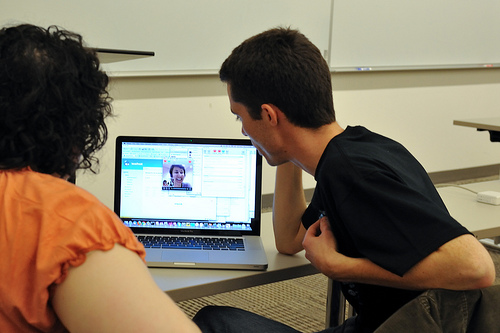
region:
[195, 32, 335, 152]
face of the person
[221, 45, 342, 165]
face of the boy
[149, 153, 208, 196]
a picture in computer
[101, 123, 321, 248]
a cool computer scren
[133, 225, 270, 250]
a key board connected to computer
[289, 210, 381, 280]
hand of the person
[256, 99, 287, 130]
ear of the person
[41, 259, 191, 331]
hand of the girl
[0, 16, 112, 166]
hairs of the girl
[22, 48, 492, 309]
two persons watching computer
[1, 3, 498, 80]
part of a white dry erase board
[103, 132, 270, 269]
a gray laptop computer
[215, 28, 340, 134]
a man's short cut hair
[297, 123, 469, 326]
part of a man's black shirt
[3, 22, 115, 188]
a woman's curly hair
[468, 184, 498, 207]
part of a white computer mouse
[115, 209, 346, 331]
part of a table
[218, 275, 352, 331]
a portion of carpet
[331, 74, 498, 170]
part of a white painted wall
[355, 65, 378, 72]
a blue and white marker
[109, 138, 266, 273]
small lap top computer on desk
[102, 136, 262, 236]
screen of laptop computer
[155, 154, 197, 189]
skype open on computer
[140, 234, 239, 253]
black computer key board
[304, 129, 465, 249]
black t-shirt on man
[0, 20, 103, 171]
curly black hair on head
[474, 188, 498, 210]
white power supply on table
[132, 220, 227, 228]
tabs open at bottom of screen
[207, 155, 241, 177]
text box open on screen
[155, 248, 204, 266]
silver track pad on front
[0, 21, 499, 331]
Man and woman looking at computer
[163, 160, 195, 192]
Woman on computer screen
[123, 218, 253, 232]
Multiple icons at bottom of computer screen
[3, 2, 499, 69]
Dry erase board in background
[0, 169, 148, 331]
Woman wearing orange shirt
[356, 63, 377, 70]
Blue dry erase marker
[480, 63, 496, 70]
Orange dry erase marker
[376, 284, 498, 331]
Guy has jacket draped on back of chair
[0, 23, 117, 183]
Woman has curly hair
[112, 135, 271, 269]
Laptop sitting on table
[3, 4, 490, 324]
people in front a laptop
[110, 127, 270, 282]
laptop is turn on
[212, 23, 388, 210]
man has black hair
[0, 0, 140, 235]
woman has black hair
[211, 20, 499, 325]
man wears a black top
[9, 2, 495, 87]
a large whiteboard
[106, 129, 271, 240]
a woman in the screen of laptop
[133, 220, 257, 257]
the keyboard is black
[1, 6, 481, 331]
two people are sitting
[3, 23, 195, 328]
woman wears an orange blouse